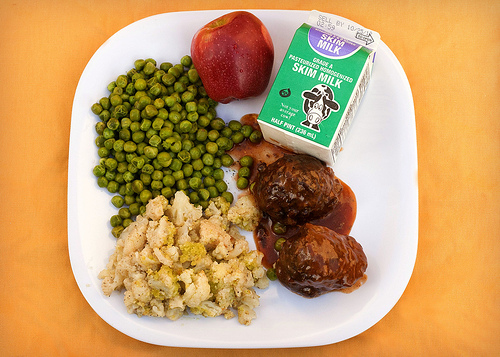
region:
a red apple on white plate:
[195, 9, 279, 96]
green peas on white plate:
[96, 65, 222, 194]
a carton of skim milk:
[277, 15, 359, 149]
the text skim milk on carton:
[315, 29, 348, 51]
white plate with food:
[370, 99, 422, 269]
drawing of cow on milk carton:
[299, 76, 342, 137]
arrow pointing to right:
[355, 24, 377, 45]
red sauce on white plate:
[324, 200, 361, 230]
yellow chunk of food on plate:
[112, 191, 272, 327]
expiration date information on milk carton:
[307, 9, 372, 39]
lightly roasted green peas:
[94, 52, 226, 197]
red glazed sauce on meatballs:
[248, 151, 375, 302]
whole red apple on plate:
[186, 5, 279, 109]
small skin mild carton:
[267, 8, 379, 165]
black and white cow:
[292, 79, 343, 142]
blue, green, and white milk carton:
[258, 3, 380, 165]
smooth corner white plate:
[54, 3, 455, 351]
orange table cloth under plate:
[15, 17, 112, 73]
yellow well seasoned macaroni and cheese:
[136, 232, 247, 304]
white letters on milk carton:
[289, 49, 355, 86]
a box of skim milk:
[276, 11, 353, 155]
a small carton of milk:
[277, 15, 364, 151]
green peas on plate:
[97, 64, 222, 201]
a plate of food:
[79, 14, 407, 329]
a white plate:
[357, 117, 426, 228]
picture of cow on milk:
[298, 85, 335, 135]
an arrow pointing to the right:
[355, 27, 379, 44]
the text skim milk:
[313, 29, 348, 59]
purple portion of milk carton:
[307, 24, 354, 59]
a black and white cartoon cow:
[300, 83, 337, 129]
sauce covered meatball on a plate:
[284, 226, 364, 296]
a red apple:
[191, 10, 272, 98]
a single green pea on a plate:
[134, 77, 145, 89]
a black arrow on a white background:
[355, 32, 373, 45]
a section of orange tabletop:
[419, 247, 499, 347]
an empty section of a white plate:
[364, 143, 413, 193]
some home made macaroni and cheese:
[100, 201, 261, 324]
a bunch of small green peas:
[95, 105, 216, 192]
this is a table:
[7, 15, 39, 73]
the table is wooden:
[7, 227, 32, 304]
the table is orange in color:
[4, 170, 51, 282]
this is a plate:
[141, 20, 176, 40]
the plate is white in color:
[268, 303, 332, 338]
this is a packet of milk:
[261, 21, 371, 156]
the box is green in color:
[293, 38, 305, 51]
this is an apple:
[192, 22, 264, 91]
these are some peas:
[128, 80, 198, 167]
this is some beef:
[290, 183, 338, 270]